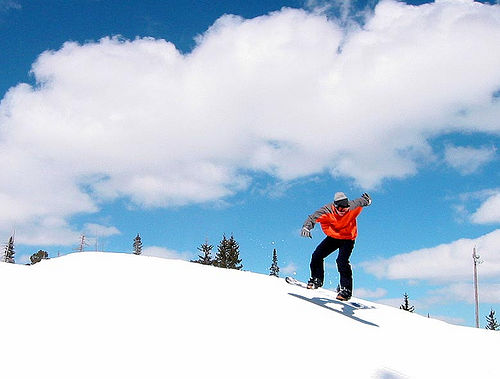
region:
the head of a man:
[331, 189, 352, 210]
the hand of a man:
[298, 226, 314, 239]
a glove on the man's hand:
[297, 225, 312, 238]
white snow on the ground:
[0, 248, 499, 377]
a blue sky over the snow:
[0, 0, 499, 331]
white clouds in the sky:
[0, 0, 499, 306]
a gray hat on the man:
[331, 190, 348, 201]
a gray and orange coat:
[302, 194, 367, 239]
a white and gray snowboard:
[283, 272, 385, 320]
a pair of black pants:
[306, 235, 358, 292]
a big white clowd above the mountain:
[1, 4, 490, 189]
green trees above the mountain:
[199, 234, 241, 268]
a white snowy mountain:
[6, 255, 495, 377]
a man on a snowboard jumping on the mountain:
[302, 192, 372, 304]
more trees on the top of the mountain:
[4, 234, 51, 267]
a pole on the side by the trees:
[465, 237, 490, 339]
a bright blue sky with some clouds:
[3, 1, 497, 306]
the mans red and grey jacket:
[303, 207, 373, 247]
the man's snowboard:
[284, 274, 372, 316]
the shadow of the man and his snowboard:
[289, 281, 384, 334]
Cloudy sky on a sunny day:
[20, 6, 495, 186]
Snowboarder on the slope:
[190, 50, 440, 330]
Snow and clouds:
[0, 65, 290, 350]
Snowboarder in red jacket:
[271, 90, 426, 341]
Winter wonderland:
[12, 52, 287, 358]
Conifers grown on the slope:
[157, 203, 284, 323]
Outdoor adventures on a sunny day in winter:
[249, 93, 433, 353]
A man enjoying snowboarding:
[88, 60, 470, 353]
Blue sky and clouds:
[13, 8, 270, 297]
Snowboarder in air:
[237, 137, 421, 327]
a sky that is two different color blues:
[3, 0, 498, 277]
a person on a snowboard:
[284, 184, 389, 315]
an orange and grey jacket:
[298, 196, 377, 244]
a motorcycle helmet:
[331, 191, 354, 216]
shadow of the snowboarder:
[291, 273, 387, 335]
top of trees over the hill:
[184, 229, 249, 274]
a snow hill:
[15, 238, 394, 377]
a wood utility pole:
[456, 230, 488, 337]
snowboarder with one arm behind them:
[292, 176, 369, 254]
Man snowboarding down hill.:
[279, 181, 376, 317]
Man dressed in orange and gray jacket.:
[298, 189, 372, 241]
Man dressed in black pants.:
[307, 234, 359, 296]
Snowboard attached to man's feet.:
[282, 271, 373, 319]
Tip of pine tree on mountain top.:
[126, 227, 251, 276]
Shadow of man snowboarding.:
[288, 287, 378, 337]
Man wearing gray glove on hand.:
[294, 221, 316, 243]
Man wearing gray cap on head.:
[330, 188, 350, 203]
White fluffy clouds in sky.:
[21, 33, 312, 214]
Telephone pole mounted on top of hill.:
[466, 238, 492, 348]